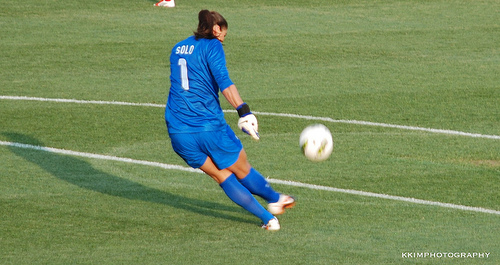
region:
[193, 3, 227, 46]
goalie has a ponytail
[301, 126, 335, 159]
soccer ball is white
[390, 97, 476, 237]
white lines on the soccer field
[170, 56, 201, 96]
white 1 on the back of jersey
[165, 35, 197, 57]
SOLO in white on the back of jersey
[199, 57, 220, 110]
jersey is bright blue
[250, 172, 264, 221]
soccer socks are blue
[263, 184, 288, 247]
cleats are white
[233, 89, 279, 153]
goalie is wearing gloves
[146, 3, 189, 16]
soccer cleat on the field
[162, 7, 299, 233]
a woman soccer player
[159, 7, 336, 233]
a woman soccer player hitting a soccor ball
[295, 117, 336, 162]
a white soccer ball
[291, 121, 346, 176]
a soccer ball in the air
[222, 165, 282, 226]
a pair of blue knee highs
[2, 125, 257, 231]
the shadow of a soccer player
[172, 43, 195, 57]
the name of a soccer player solo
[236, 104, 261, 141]
a single white glove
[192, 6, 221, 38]
a brown pony tail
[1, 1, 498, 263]
a green soccer field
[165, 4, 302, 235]
A woman playing soccer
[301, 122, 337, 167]
The soccer ball is fuzzy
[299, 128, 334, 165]
The soccer ball is in the air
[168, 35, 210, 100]
A number and lettering on a jersey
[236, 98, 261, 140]
A soccer mitt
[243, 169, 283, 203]
The sock is blue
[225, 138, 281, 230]
The socks go up to her knee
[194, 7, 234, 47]
Girl is wearing a pony tail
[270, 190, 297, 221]
Shoe has red and white coloring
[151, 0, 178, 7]
A single sneaker in the field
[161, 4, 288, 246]
this is a lady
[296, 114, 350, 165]
this is a ball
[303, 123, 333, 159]
the ball is white in color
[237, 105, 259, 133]
this is a glove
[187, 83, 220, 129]
this is a t shirt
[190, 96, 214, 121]
the t shirt is blue in color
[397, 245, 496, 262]
this is a writing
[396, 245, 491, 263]
the writing is in white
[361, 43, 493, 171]
this is a grass area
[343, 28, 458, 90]
the grass is green in color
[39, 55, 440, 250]
Ground is green color.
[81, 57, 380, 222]
White lines in ground.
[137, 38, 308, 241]
player is blue dress.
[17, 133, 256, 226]
Shadow is falling in ground.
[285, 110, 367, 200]
ball is white and black color.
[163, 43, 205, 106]
1 is written in player shirt.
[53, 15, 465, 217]
Day time picture.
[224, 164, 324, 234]
player is wearing blue socks.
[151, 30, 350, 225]
player is trying to kick the ball.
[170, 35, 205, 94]
Letters are white color.